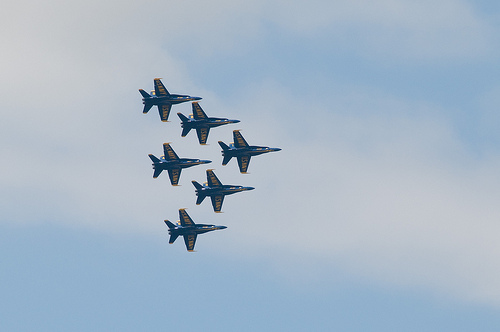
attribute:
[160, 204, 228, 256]
jet — blue and yellow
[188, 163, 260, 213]
jet — blue and yellow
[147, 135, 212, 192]
jet — blue and yellow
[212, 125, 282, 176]
jet — blue and yellow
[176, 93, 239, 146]
jet — blue and yellow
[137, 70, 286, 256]
jets — six, yellow, blue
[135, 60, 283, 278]
planes — blue, yellow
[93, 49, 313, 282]
planes — Blue 